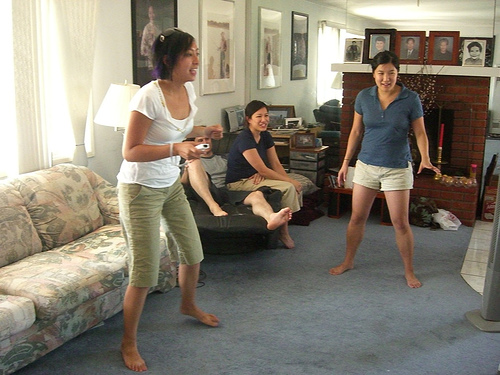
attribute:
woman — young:
[114, 30, 220, 372]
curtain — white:
[38, 20, 115, 140]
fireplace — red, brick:
[340, 73, 479, 225]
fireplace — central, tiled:
[330, 58, 494, 228]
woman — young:
[323, 48, 436, 290]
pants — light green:
[114, 177, 204, 289]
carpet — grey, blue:
[10, 200, 499, 373]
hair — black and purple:
[113, 5, 274, 148]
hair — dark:
[147, 26, 194, 78]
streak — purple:
[149, 46, 160, 78]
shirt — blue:
[353, 84, 426, 170]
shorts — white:
[352, 156, 414, 193]